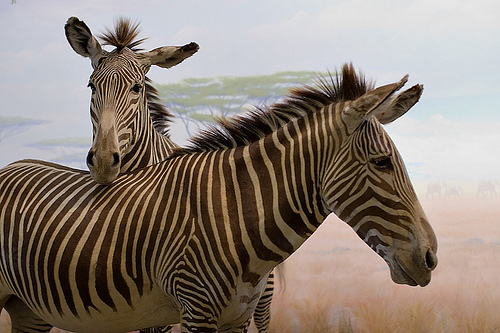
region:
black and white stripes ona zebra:
[158, 174, 203, 225]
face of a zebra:
[52, 15, 183, 183]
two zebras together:
[4, 14, 454, 329]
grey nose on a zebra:
[398, 233, 440, 295]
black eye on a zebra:
[377, 144, 397, 185]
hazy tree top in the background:
[200, 58, 272, 106]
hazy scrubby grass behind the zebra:
[310, 258, 365, 326]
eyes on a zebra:
[81, 75, 146, 105]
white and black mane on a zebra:
[222, 104, 297, 142]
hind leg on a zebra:
[254, 280, 284, 331]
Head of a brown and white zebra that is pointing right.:
[308, 73, 441, 286]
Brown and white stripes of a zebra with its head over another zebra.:
[64, 18, 200, 183]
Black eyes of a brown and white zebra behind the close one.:
[88, 81, 140, 94]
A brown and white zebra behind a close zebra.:
[63, 15, 287, 332]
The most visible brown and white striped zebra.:
[1, 62, 438, 332]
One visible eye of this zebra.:
[371, 153, 389, 168]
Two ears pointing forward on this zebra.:
[339, 73, 424, 132]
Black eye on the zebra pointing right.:
[371, 157, 388, 167]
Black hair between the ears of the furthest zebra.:
[97, 14, 152, 54]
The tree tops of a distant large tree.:
[150, 70, 345, 143]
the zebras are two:
[10, 9, 435, 329]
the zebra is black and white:
[19, 82, 434, 316]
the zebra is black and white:
[50, 24, 167, 180]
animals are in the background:
[417, 163, 499, 211]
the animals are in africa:
[1, 8, 496, 331]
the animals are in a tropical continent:
[5, 2, 490, 331]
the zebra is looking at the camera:
[60, 39, 184, 175]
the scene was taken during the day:
[9, 7, 486, 323]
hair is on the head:
[95, 14, 143, 54]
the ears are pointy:
[330, 69, 443, 136]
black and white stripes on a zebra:
[181, 168, 282, 218]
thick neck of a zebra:
[217, 138, 324, 286]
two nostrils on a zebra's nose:
[82, 141, 124, 185]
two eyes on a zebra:
[85, 73, 139, 105]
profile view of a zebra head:
[324, 58, 462, 303]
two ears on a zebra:
[61, 13, 196, 80]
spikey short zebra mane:
[241, 83, 336, 143]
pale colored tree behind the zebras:
[191, 65, 282, 120]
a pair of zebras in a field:
[47, 17, 465, 328]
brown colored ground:
[318, 263, 365, 331]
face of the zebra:
[67, 21, 175, 208]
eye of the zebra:
[357, 149, 406, 192]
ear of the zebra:
[328, 59, 406, 151]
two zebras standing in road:
[53, 19, 418, 330]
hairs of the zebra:
[176, 74, 394, 108]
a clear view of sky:
[21, 13, 491, 197]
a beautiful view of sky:
[6, 24, 465, 174]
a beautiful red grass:
[304, 229, 486, 314]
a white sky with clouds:
[183, 7, 498, 75]